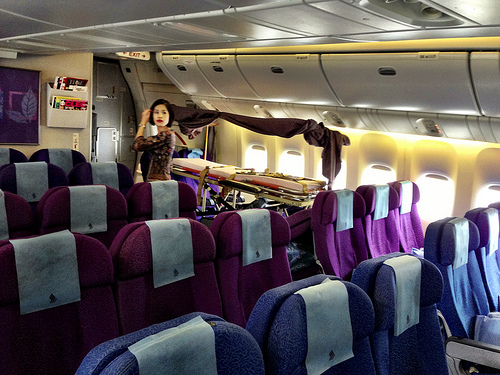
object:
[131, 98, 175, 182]
woman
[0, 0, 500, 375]
plane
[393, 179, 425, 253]
seats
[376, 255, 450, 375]
seats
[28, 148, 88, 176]
seats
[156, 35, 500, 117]
storage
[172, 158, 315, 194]
stretcher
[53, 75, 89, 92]
magazines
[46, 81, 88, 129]
rack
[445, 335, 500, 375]
armrest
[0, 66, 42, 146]
painting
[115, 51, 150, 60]
sign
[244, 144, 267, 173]
windows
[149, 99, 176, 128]
hair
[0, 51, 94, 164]
wall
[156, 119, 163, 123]
lipstick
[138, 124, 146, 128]
watch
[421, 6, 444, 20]
light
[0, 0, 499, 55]
ceiling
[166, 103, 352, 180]
curtain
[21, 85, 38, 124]
leaves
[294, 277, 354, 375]
cover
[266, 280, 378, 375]
headrest